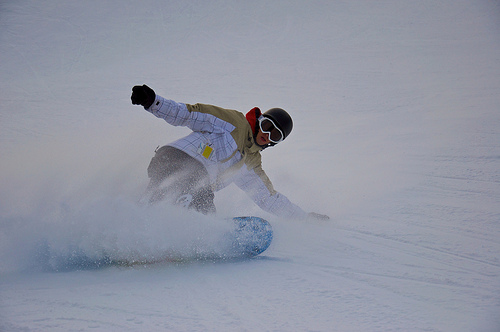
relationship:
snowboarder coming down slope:
[130, 82, 326, 222] [2, 3, 496, 330]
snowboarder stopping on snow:
[130, 82, 326, 222] [1, 2, 496, 331]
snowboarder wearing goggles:
[130, 82, 326, 222] [257, 116, 285, 144]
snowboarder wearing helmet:
[130, 82, 326, 222] [263, 109, 291, 137]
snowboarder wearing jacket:
[130, 82, 326, 222] [149, 98, 306, 220]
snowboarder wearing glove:
[130, 82, 326, 222] [130, 84, 155, 106]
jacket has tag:
[149, 98, 306, 220] [203, 144, 214, 161]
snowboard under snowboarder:
[40, 216, 272, 266] [130, 82, 326, 222]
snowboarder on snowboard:
[130, 82, 326, 222] [40, 216, 272, 266]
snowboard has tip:
[40, 216, 272, 266] [231, 214, 273, 257]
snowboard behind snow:
[40, 216, 272, 266] [1, 2, 496, 331]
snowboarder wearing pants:
[130, 82, 326, 222] [148, 147, 215, 218]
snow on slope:
[1, 2, 496, 331] [2, 3, 496, 330]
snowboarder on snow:
[130, 82, 326, 222] [1, 2, 496, 331]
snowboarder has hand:
[130, 82, 326, 222] [311, 212, 330, 222]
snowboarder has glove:
[130, 82, 326, 222] [130, 84, 155, 106]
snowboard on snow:
[40, 216, 272, 266] [1, 2, 496, 331]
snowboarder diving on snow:
[130, 82, 326, 222] [1, 2, 496, 331]